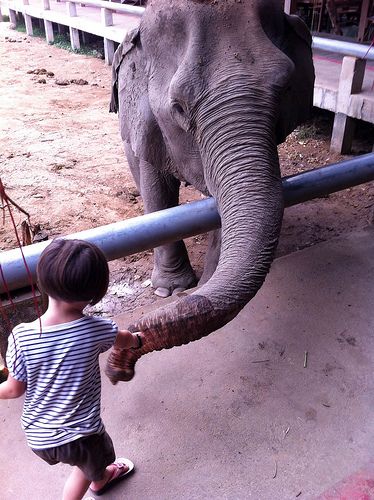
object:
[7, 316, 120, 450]
stripes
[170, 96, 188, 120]
eye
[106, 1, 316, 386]
elephant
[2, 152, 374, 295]
barrier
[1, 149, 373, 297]
bar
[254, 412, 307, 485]
twigs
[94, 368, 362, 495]
ground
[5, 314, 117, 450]
shirt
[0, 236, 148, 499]
child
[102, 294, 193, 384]
child touching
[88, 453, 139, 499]
child wearing sandal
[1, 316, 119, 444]
stripped shirt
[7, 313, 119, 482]
child's shirt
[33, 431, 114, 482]
grey shorts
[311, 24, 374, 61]
long grey tube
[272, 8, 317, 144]
ear of elephant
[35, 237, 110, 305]
"short hair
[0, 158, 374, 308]
metal pole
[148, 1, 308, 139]
grey elphant face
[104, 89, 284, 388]
elephant trunk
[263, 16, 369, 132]
platform for people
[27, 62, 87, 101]
elephant dung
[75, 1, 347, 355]
an enclosure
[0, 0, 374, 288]
enclosure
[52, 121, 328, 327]
dirt surface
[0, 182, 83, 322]
twigs on the ground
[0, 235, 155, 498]
child playing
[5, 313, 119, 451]
shirt on the child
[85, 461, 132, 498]
child's foot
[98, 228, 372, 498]
concrete area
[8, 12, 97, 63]
grass on the ground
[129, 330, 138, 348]
girl's wrist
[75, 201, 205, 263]
metal rail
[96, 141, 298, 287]
muddy ground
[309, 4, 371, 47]
railing behind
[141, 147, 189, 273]
front right leg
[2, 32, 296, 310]
ground is brown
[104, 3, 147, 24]
rail near trunk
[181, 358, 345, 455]
brown concrete